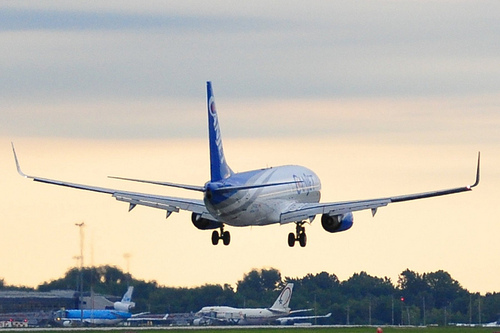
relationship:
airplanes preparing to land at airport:
[192, 281, 316, 326] [3, 284, 498, 331]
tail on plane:
[199, 79, 239, 189] [53, 46, 483, 278]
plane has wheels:
[53, 46, 483, 278] [207, 220, 313, 250]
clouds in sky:
[3, 7, 497, 271] [5, 3, 498, 287]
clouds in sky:
[0, 0, 496, 164] [5, 3, 498, 287]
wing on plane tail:
[95, 171, 212, 197] [203, 79, 229, 181]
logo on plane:
[281, 161, 328, 196] [123, 73, 460, 285]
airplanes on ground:
[192, 282, 335, 325] [0, 322, 500, 332]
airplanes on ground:
[53, 290, 164, 326] [0, 322, 500, 332]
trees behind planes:
[390, 270, 499, 325] [9, 78, 479, 245]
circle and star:
[279, 286, 291, 308] [276, 297, 283, 304]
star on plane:
[276, 297, 283, 304] [195, 282, 313, 324]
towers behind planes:
[71, 217, 133, 275] [10, 80, 479, 322]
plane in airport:
[53, 46, 483, 278] [4, 286, 78, 313]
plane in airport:
[53, 46, 483, 278] [3, 253, 493, 327]